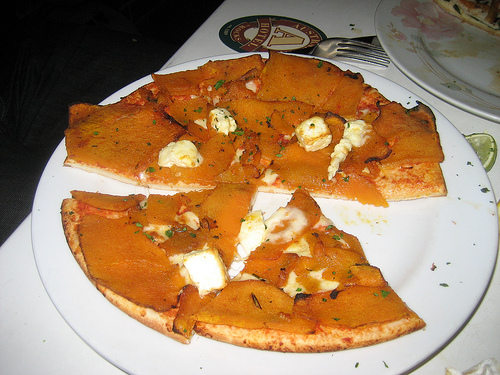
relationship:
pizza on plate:
[62, 66, 451, 366] [34, 43, 479, 373]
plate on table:
[34, 43, 479, 373] [2, 1, 498, 374]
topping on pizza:
[183, 244, 233, 296] [62, 66, 451, 366]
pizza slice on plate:
[195, 187, 425, 353] [34, 43, 479, 373]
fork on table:
[308, 35, 391, 67] [2, 1, 498, 374]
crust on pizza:
[197, 312, 428, 352] [62, 66, 451, 366]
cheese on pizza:
[157, 140, 204, 170] [62, 66, 451, 366]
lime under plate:
[464, 133, 496, 171] [34, 43, 479, 373]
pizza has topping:
[62, 66, 451, 366] [183, 244, 233, 296]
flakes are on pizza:
[232, 95, 298, 163] [62, 66, 451, 366]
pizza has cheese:
[62, 66, 451, 366] [157, 140, 204, 170]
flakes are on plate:
[427, 145, 500, 295] [34, 43, 479, 373]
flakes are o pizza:
[232, 95, 298, 163] [62, 66, 451, 366]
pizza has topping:
[62, 66, 451, 366] [183, 244, 232, 288]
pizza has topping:
[62, 66, 451, 366] [370, 285, 388, 300]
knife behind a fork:
[356, 34, 383, 45] [308, 35, 391, 67]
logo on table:
[217, 15, 326, 54] [182, 8, 351, 46]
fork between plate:
[308, 35, 391, 67] [34, 43, 479, 373]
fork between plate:
[308, 35, 391, 67] [370, 0, 480, 74]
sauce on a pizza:
[379, 165, 441, 190] [62, 66, 451, 366]